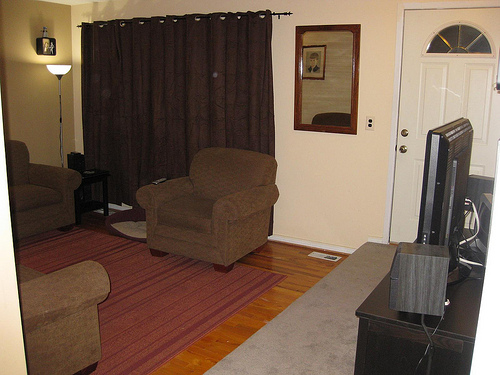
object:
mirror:
[292, 23, 362, 136]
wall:
[270, 0, 397, 247]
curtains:
[78, 8, 276, 237]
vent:
[308, 251, 343, 263]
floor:
[145, 239, 352, 374]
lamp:
[45, 64, 73, 168]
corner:
[62, 47, 90, 157]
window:
[421, 20, 497, 59]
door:
[383, 3, 500, 246]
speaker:
[67, 151, 87, 174]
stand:
[73, 168, 109, 225]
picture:
[302, 45, 327, 81]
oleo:
[35, 25, 57, 56]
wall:
[0, 3, 85, 172]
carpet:
[198, 240, 401, 374]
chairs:
[6, 139, 85, 244]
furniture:
[0, 258, 112, 374]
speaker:
[386, 241, 451, 318]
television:
[416, 116, 474, 287]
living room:
[0, 0, 499, 375]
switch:
[365, 116, 376, 132]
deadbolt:
[401, 129, 410, 138]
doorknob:
[398, 145, 408, 154]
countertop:
[354, 271, 494, 356]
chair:
[134, 146, 280, 275]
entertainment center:
[353, 116, 494, 375]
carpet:
[0, 224, 289, 374]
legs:
[212, 262, 234, 274]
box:
[35, 36, 56, 55]